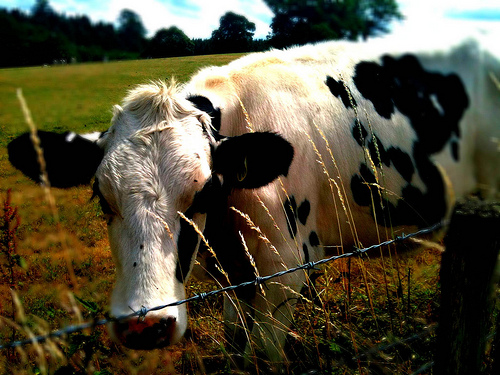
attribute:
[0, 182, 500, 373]
fence — barbed wire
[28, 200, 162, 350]
plant — red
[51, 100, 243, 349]
head — black and white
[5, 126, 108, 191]
ear — furry, black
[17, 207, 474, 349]
fence — barbed, wire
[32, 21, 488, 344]
cow — black and white, spotted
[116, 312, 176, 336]
nose — pink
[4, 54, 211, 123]
grass — green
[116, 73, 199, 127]
hair — tuft, white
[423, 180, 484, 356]
post — wooden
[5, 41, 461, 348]
field — green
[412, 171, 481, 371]
post — wooden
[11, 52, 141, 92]
hill — small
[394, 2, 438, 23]
clouds — white